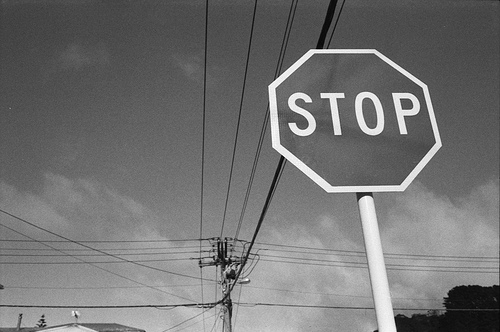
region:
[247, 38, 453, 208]
black and white stop sign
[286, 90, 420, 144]
white lettering on a black sign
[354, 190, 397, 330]
sign on a white pole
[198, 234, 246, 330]
tall utility pole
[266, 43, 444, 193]
white border on a stop sign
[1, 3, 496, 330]
wires attached to a utility pole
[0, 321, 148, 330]
roof on a house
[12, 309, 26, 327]
chimney on a roof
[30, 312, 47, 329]
tree showing over the top of a roof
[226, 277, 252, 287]
street light on a utility pole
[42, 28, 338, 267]
the photo is in black and white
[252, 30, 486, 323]
the stop sign is red and white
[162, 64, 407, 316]
the power lines are above the stop sign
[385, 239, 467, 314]
the trees are tall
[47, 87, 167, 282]
the sky is cloudy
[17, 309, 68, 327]
the tree is behind the roof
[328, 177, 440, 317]
a metal pole holds the sign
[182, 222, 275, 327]
a light pole is by the power lines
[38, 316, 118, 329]
the roof is arched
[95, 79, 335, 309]
the sky is hazy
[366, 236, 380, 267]
part of a posdt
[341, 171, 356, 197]
edge of a line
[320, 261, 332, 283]
part of a cloud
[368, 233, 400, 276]
art of a post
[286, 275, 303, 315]
part of a cloud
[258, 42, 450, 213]
a stop sign on a pole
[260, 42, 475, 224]
an octagon shaped sign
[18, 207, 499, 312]
wires in the sky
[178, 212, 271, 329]
a pole connected to wires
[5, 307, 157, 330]
a partial top of a house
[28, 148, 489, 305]
white wispy clouds in the sky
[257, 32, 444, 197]
a sign with a white boarder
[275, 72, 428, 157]
white letters on a sign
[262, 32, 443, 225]
a sign indicating to stop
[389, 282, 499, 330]
the tops of some trees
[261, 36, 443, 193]
sign with white border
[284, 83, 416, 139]
white lettering on sign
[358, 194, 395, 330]
pole sign is affixed to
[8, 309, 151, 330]
roof of the house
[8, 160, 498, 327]
wispy clouds in the sky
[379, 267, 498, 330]
treetops on the right side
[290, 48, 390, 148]
shadows on the sign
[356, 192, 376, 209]
shadow on the pole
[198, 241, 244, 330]
utility pole power lines are attached to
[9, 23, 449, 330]
power lines running to utility pole